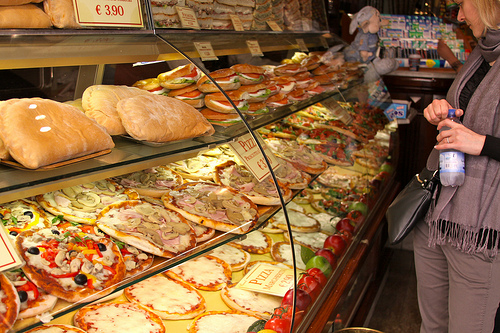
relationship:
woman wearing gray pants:
[413, 0, 497, 331] [407, 185, 498, 331]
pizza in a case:
[93, 195, 200, 262] [12, 27, 318, 331]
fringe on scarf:
[467, 229, 479, 257] [421, 42, 500, 259]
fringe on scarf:
[452, 226, 461, 254] [421, 42, 500, 259]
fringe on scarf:
[449, 223, 460, 248] [421, 42, 500, 259]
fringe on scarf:
[483, 226, 489, 253] [421, 42, 500, 259]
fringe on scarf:
[436, 214, 446, 244] [421, 42, 500, 259]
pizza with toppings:
[160, 180, 256, 236] [191, 191, 225, 211]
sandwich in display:
[157, 62, 201, 90] [0, 0, 403, 333]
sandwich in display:
[230, 62, 264, 84] [0, 0, 403, 333]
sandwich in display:
[203, 90, 249, 113] [0, 0, 403, 333]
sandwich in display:
[195, 68, 241, 93] [0, 0, 403, 333]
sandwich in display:
[170, 83, 205, 107] [0, 0, 403, 333]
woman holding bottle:
[389, 0, 500, 333] [437, 108, 466, 187]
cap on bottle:
[447, 107, 457, 117] [437, 107, 467, 185]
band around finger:
[444, 137, 455, 144] [440, 137, 456, 142]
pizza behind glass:
[93, 195, 200, 262] [93, 138, 340, 325]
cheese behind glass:
[198, 262, 222, 277] [117, 176, 333, 328]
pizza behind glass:
[82, 305, 162, 333] [10, 138, 359, 330]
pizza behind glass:
[126, 271, 204, 318] [10, 138, 359, 330]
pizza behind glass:
[169, 254, 231, 291] [10, 138, 359, 330]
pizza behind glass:
[189, 306, 258, 333] [10, 138, 359, 330]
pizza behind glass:
[223, 285, 285, 317] [10, 138, 359, 330]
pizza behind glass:
[93, 195, 200, 262] [152, 25, 398, 331]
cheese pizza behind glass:
[316, 142, 353, 167] [152, 25, 398, 331]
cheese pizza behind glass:
[296, 127, 344, 143] [152, 25, 398, 331]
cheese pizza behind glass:
[323, 116, 366, 138] [152, 25, 398, 331]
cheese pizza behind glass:
[261, 122, 298, 135] [152, 25, 398, 331]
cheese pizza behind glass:
[281, 114, 317, 129] [152, 25, 398, 331]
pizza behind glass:
[213, 161, 291, 204] [184, 16, 382, 192]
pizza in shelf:
[10, 221, 128, 302] [4, 23, 394, 324]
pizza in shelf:
[93, 195, 200, 262] [4, 23, 394, 324]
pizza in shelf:
[161, 177, 264, 237] [4, 23, 394, 324]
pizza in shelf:
[211, 154, 296, 208] [4, 23, 394, 324]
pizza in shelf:
[121, 266, 208, 321] [4, 23, 394, 324]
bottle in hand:
[437, 107, 464, 187] [434, 120, 487, 156]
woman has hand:
[413, 0, 497, 331] [434, 120, 487, 156]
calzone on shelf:
[2, 91, 117, 169] [0, 127, 227, 211]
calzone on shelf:
[113, 92, 231, 147] [0, 127, 227, 211]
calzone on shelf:
[83, 77, 151, 131] [0, 127, 227, 211]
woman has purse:
[389, 0, 500, 333] [377, 144, 438, 245]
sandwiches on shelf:
[194, 60, 311, 116] [4, 23, 394, 324]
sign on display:
[194, 41, 217, 61] [0, 0, 403, 333]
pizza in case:
[10, 212, 129, 302] [1, 15, 408, 331]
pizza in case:
[169, 254, 231, 291] [1, 15, 408, 331]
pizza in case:
[93, 195, 200, 262] [31, 37, 417, 319]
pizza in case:
[93, 195, 200, 262] [16, 65, 301, 324]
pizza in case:
[160, 180, 256, 236] [16, 65, 301, 324]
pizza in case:
[10, 221, 128, 302] [16, 65, 301, 324]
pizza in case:
[140, 275, 197, 312] [16, 65, 301, 324]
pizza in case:
[169, 254, 231, 291] [16, 65, 301, 324]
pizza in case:
[223, 285, 285, 317] [16, 65, 301, 324]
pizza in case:
[82, 305, 152, 327] [16, 65, 301, 324]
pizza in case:
[209, 306, 247, 325] [1, 15, 408, 331]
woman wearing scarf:
[389, 0, 500, 333] [409, 42, 485, 250]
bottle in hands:
[437, 108, 466, 187] [425, 97, 477, 155]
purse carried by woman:
[374, 156, 459, 245] [364, 2, 497, 330]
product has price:
[42, 0, 84, 27] [93, 4, 126, 21]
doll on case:
[345, 0, 389, 75] [26, 48, 388, 306]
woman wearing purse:
[413, 0, 497, 331] [386, 165, 441, 242]